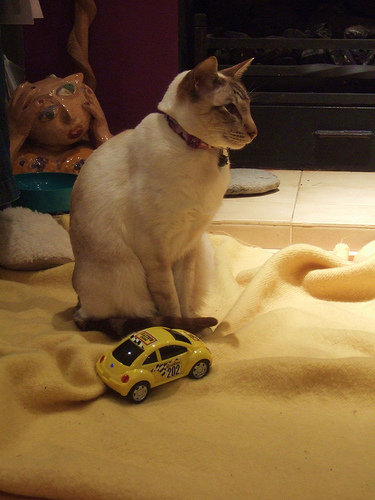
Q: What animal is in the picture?
A: Cat.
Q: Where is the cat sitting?
A: Floor.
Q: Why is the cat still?
A: Looking.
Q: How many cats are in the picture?
A: One.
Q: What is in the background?
A: Fireplace.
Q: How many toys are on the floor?
A: One.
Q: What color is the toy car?
A: Yellow.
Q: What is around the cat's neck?
A: Collar.